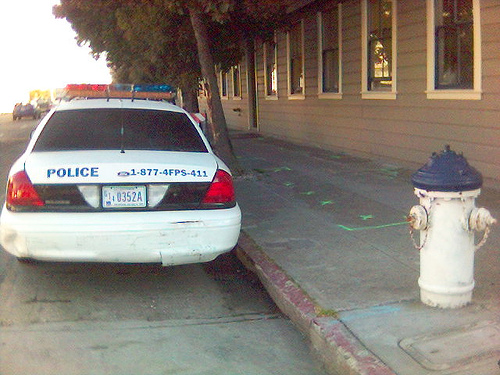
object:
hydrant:
[405, 142, 499, 309]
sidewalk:
[202, 113, 500, 373]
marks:
[283, 182, 294, 187]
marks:
[302, 191, 315, 196]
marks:
[321, 200, 333, 205]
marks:
[358, 214, 374, 221]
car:
[0, 83, 243, 268]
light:
[63, 83, 177, 99]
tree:
[50, 0, 293, 180]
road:
[242, 210, 421, 371]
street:
[0, 261, 281, 373]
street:
[2, 109, 332, 373]